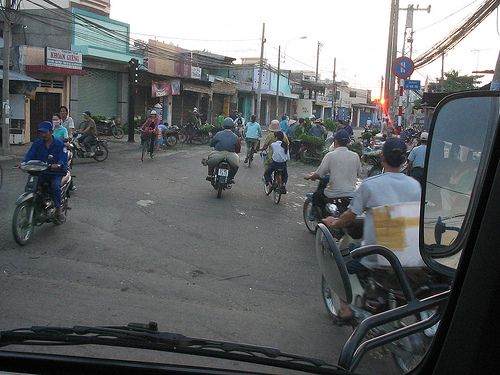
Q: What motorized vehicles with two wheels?
A: Motorcycles.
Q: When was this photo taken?
A: During the daytime.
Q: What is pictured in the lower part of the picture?
A: A windshield wiper.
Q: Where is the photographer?
A: On the bus.